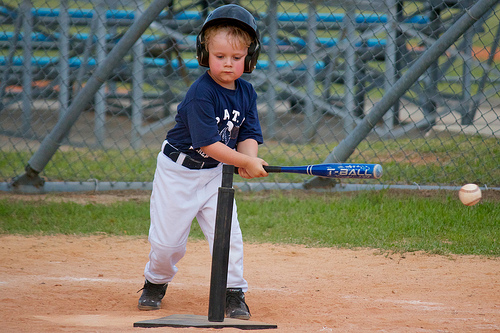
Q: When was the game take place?
A: Daytime.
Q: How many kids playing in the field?
A: One.